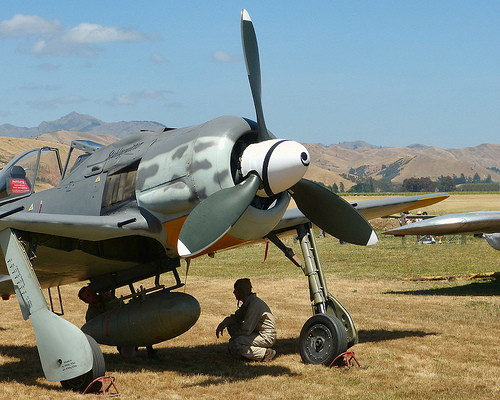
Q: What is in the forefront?
A: A plane.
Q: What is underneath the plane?
A: A person.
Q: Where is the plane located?
A: In an outside field.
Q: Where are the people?
A: Under the plane.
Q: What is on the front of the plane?
A: A propeller.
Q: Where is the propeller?
A: Front of the plane.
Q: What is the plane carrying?
A: A bomb.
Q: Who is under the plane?
A: Two people.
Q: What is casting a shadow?
A: The plane.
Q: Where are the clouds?
A: Above the mountains.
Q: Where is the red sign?
A: Inside the plane.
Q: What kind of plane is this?
A: An old fighter plane.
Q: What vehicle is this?
A: Propeller.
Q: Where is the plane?
A: Field.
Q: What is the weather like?
A: Mostly sunny.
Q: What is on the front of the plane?
A: Propeller.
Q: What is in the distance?
A: Mountains.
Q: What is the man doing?
A: Sitting.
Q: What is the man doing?
A: Repairs.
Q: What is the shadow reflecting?
A: The jet.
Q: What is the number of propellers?
A: Three.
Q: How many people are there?
A: One.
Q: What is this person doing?
A: Kneeling.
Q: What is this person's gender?
A: Male.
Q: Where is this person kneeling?
A: Under the airplane.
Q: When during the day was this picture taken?
A: Daytime.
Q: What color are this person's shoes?
A: Brown.